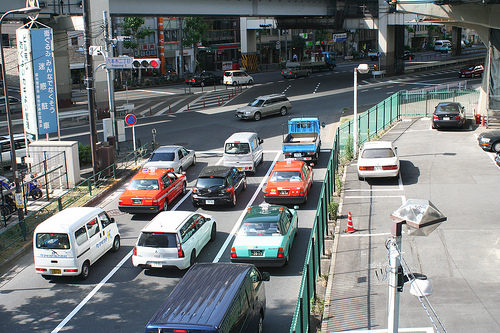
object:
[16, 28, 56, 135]
sign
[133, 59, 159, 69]
traffic light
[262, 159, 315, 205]
red car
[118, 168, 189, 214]
red car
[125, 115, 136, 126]
sign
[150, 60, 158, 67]
light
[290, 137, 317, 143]
bed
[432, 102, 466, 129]
car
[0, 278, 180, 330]
shade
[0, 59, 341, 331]
road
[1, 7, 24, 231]
pole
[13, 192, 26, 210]
sign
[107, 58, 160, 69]
white signal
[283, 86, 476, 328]
fence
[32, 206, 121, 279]
car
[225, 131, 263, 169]
car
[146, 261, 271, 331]
grey house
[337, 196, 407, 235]
parking lot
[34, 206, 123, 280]
van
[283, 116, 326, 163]
truck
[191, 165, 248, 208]
sedan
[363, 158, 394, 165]
shiny white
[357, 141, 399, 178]
car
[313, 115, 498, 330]
street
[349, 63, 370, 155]
light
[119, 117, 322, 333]
traffic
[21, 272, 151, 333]
tree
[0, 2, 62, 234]
lamp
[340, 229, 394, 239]
lines